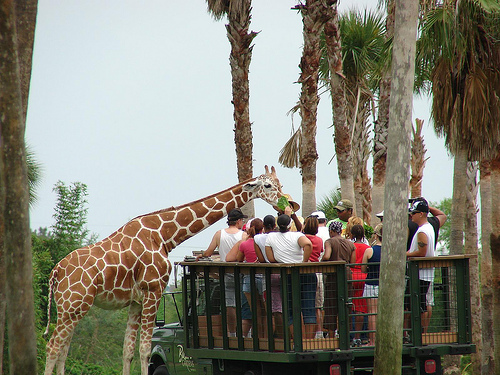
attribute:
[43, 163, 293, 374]
giraffe — looking, captive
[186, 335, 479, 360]
platform — raised, green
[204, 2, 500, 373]
trees — tall, limbless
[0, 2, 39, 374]
trees — tall, limbless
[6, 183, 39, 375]
trunk — brown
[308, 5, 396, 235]
tree — palm, tall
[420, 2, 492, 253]
tree — palm, palmetto, growing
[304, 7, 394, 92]
palm — green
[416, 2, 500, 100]
palm — green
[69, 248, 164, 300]
spots — brown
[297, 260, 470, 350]
fence — painted, green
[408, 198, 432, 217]
cap — black, white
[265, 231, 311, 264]
shirt — white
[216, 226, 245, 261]
shirt — white, sleeveless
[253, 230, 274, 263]
shirt — white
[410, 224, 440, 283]
shirt — white, sleeveless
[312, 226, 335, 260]
shirt — white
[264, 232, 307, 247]
sleeves — short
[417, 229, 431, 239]
sleeves — short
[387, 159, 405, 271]
bark — missing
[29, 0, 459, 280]
sky — cloudy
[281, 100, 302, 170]
leaf — dried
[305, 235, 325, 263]
shirt — red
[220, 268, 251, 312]
shorts — white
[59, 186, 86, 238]
leaves — green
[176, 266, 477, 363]
deck — wooden, painted, green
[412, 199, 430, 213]
color — dark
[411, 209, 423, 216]
sunglasses — black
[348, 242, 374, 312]
outfit — orange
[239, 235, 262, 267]
shirt — pink, sleeveless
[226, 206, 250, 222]
cap — black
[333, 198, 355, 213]
cap — grey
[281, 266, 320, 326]
capris — blue, jean